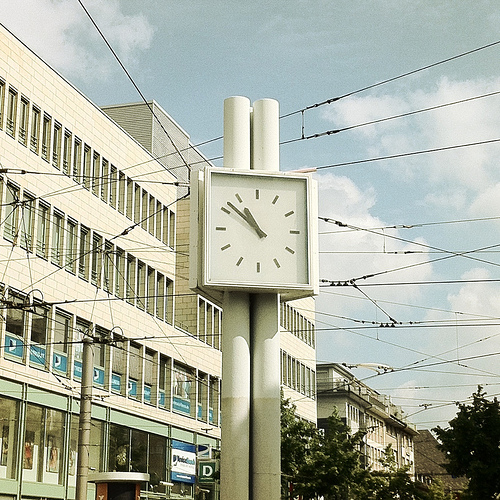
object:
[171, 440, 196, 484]
sign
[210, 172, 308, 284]
face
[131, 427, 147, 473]
window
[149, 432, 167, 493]
window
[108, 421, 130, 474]
window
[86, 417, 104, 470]
window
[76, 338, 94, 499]
utility pole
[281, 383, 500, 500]
trees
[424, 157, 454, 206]
ground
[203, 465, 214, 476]
d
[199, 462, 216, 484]
sign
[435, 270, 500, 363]
cloud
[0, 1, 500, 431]
sky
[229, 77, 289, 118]
ground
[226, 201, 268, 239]
hands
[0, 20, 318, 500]
building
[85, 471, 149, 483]
awning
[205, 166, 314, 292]
pole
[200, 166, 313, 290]
clock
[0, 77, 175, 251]
blinds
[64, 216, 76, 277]
windows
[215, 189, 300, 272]
number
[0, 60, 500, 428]
lines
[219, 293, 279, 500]
pole